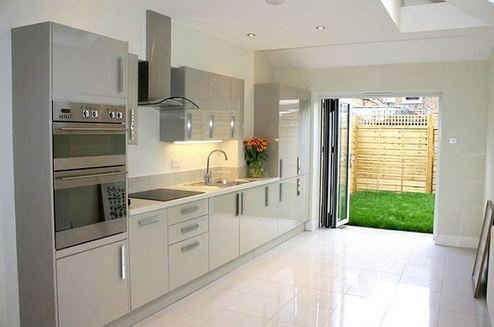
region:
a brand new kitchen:
[18, 9, 492, 324]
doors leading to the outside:
[311, 73, 463, 245]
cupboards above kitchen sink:
[161, 58, 274, 167]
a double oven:
[44, 70, 166, 287]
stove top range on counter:
[106, 157, 216, 235]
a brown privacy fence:
[347, 99, 435, 232]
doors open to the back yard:
[321, 94, 440, 227]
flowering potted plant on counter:
[246, 134, 270, 176]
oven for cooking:
[45, 92, 132, 245]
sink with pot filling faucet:
[188, 147, 251, 190]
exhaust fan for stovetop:
[139, 13, 197, 125]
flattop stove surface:
[125, 186, 201, 200]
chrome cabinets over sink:
[170, 68, 244, 141]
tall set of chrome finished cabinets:
[259, 80, 314, 236]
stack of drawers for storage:
[167, 191, 217, 286]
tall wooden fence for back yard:
[358, 116, 435, 192]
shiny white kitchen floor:
[255, 262, 350, 300]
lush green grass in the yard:
[357, 190, 414, 221]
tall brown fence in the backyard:
[365, 116, 430, 187]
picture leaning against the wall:
[467, 199, 487, 297]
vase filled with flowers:
[237, 123, 281, 179]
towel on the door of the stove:
[93, 172, 145, 240]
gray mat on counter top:
[128, 180, 216, 211]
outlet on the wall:
[444, 133, 465, 153]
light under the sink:
[176, 128, 243, 170]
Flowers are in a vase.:
[242, 135, 273, 182]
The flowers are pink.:
[239, 136, 271, 176]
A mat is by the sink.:
[129, 187, 203, 206]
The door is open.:
[320, 94, 437, 234]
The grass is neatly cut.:
[344, 188, 435, 232]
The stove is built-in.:
[47, 99, 130, 250]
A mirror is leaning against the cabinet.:
[465, 201, 493, 299]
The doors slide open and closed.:
[317, 100, 359, 231]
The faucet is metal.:
[197, 148, 232, 186]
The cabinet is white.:
[208, 194, 243, 263]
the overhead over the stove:
[145, 17, 195, 198]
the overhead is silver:
[141, 15, 178, 107]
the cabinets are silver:
[174, 62, 247, 133]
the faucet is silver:
[205, 146, 221, 186]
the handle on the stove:
[56, 171, 127, 186]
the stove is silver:
[57, 173, 130, 239]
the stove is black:
[138, 182, 192, 203]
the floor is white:
[294, 230, 436, 313]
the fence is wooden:
[354, 125, 436, 199]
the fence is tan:
[352, 124, 428, 194]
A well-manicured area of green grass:
[346, 187, 435, 232]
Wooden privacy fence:
[350, 120, 429, 188]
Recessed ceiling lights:
[239, 18, 325, 42]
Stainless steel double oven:
[44, 94, 127, 249]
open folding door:
[321, 97, 352, 227]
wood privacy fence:
[349, 113, 433, 199]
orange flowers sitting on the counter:
[240, 137, 269, 180]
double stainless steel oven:
[50, 99, 129, 251]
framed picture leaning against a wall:
[470, 198, 491, 298]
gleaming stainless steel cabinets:
[158, 66, 244, 140]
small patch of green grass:
[350, 189, 435, 232]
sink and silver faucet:
[184, 141, 249, 198]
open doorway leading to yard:
[306, 83, 444, 246]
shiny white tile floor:
[167, 247, 471, 324]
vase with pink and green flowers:
[241, 122, 280, 181]